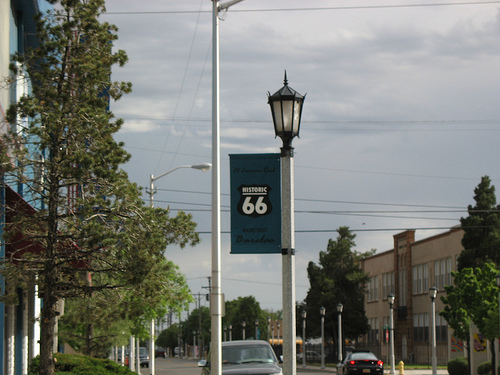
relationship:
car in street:
[118, 340, 157, 368] [143, 339, 220, 374]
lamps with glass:
[256, 53, 320, 173] [258, 78, 316, 144]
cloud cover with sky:
[36, 1, 498, 334] [34, 1, 498, 330]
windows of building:
[356, 251, 461, 302] [356, 207, 498, 370]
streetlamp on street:
[416, 283, 447, 373] [143, 351, 210, 371]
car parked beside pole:
[211, 337, 282, 373] [209, 10, 225, 373]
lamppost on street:
[333, 299, 345, 361] [134, 354, 340, 373]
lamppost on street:
[427, 285, 440, 374] [134, 354, 340, 373]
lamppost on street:
[317, 302, 328, 369] [134, 354, 340, 373]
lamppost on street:
[384, 289, 399, 373] [134, 354, 340, 373]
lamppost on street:
[266, 65, 310, 374] [134, 354, 340, 373]